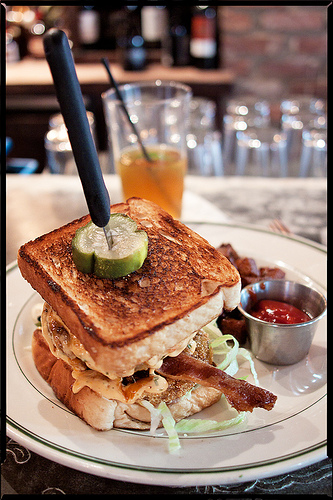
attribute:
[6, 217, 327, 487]
plate — round, white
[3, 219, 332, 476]
lining — green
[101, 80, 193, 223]
glass — clear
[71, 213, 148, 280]
pickle — sliced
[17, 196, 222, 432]
bread — toasted, brown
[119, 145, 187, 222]
liquid — yellow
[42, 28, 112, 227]
handle — black